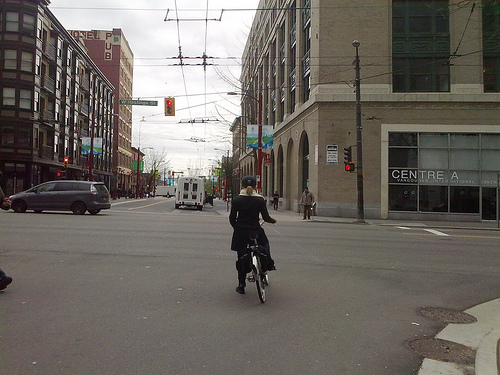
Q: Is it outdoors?
A: Yes, it is outdoors.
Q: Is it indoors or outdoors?
A: It is outdoors.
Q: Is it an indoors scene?
A: No, it is outdoors.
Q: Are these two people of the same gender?
A: No, they are both male and female.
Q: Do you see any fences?
A: No, there are no fences.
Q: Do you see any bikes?
A: Yes, there is a bike.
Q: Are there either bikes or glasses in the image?
A: Yes, there is a bike.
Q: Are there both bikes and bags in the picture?
A: No, there is a bike but no bags.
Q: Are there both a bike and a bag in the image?
A: No, there is a bike but no bags.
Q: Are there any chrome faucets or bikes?
A: Yes, there is a chrome bike.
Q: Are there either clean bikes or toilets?
A: Yes, there is a clean bike.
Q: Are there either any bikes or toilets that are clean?
A: Yes, the bike is clean.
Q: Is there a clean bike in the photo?
A: Yes, there is a clean bike.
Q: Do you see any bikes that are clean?
A: Yes, there is a bike that is clean.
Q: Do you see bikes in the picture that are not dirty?
A: Yes, there is a clean bike.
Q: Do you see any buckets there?
A: No, there are no buckets.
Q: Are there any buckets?
A: No, there are no buckets.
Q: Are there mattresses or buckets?
A: No, there are no buckets or mattresses.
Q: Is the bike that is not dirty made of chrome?
A: Yes, the bike is made of chrome.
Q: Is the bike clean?
A: Yes, the bike is clean.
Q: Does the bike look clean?
A: Yes, the bike is clean.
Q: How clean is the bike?
A: The bike is clean.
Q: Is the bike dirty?
A: No, the bike is clean.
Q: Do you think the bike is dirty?
A: No, the bike is clean.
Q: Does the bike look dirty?
A: No, the bike is clean.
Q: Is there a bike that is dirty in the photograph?
A: No, there is a bike but it is clean.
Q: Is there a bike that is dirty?
A: No, there is a bike but it is clean.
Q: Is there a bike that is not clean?
A: No, there is a bike but it is clean.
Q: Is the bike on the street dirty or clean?
A: The bike is clean.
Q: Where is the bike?
A: The bike is on the street.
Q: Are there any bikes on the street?
A: Yes, there is a bike on the street.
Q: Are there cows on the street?
A: No, there is a bike on the street.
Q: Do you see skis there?
A: No, there are no skis.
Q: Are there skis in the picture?
A: No, there are no skis.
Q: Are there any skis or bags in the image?
A: No, there are no skis or bags.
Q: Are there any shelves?
A: No, there are no shelves.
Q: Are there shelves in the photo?
A: No, there are no shelves.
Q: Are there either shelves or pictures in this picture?
A: No, there are no shelves or pictures.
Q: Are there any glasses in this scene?
A: No, there are no glasses.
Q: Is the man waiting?
A: Yes, the man is waiting.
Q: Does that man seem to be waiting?
A: Yes, the man is waiting.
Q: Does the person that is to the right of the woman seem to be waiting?
A: Yes, the man is waiting.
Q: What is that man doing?
A: The man is waiting.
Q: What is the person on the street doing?
A: The man is waiting.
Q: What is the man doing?
A: The man is waiting.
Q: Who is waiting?
A: The man is waiting.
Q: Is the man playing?
A: No, the man is waiting.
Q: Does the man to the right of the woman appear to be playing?
A: No, the man is waiting.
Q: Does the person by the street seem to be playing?
A: No, the man is waiting.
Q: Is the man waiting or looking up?
A: The man is waiting.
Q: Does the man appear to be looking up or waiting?
A: The man is waiting.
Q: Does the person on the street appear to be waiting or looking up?
A: The man is waiting.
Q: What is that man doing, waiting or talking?
A: The man is waiting.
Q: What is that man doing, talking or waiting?
A: The man is waiting.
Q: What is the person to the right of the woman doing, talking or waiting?
A: The man is waiting.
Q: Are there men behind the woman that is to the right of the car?
A: Yes, there is a man behind the woman.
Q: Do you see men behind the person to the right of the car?
A: Yes, there is a man behind the woman.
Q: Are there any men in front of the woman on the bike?
A: No, the man is behind the woman.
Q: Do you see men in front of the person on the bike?
A: No, the man is behind the woman.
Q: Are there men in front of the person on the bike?
A: No, the man is behind the woman.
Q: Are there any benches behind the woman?
A: No, there is a man behind the woman.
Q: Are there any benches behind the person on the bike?
A: No, there is a man behind the woman.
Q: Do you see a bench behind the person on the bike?
A: No, there is a man behind the woman.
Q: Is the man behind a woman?
A: Yes, the man is behind a woman.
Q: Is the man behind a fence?
A: No, the man is behind a woman.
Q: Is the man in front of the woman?
A: No, the man is behind the woman.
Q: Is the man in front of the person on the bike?
A: No, the man is behind the woman.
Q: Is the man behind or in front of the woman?
A: The man is behind the woman.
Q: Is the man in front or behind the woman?
A: The man is behind the woman.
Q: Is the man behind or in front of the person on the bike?
A: The man is behind the woman.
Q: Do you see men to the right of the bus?
A: Yes, there is a man to the right of the bus.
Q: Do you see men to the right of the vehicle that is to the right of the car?
A: Yes, there is a man to the right of the bus.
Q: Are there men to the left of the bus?
A: No, the man is to the right of the bus.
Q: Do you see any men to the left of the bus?
A: No, the man is to the right of the bus.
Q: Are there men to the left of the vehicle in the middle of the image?
A: No, the man is to the right of the bus.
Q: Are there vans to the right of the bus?
A: No, there is a man to the right of the bus.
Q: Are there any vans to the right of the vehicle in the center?
A: No, there is a man to the right of the bus.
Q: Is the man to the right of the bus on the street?
A: Yes, the man is to the right of the bus.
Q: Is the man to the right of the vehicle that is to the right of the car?
A: Yes, the man is to the right of the bus.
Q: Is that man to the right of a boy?
A: No, the man is to the right of the bus.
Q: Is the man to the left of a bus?
A: No, the man is to the right of a bus.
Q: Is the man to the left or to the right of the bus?
A: The man is to the right of the bus.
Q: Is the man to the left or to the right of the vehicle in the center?
A: The man is to the right of the bus.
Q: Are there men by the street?
A: Yes, there is a man by the street.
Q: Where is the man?
A: The man is on the street.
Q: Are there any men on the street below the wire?
A: Yes, there is a man on the street.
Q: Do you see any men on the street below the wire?
A: Yes, there is a man on the street.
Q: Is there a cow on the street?
A: No, there is a man on the street.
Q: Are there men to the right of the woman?
A: Yes, there is a man to the right of the woman.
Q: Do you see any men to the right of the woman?
A: Yes, there is a man to the right of the woman.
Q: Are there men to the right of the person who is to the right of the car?
A: Yes, there is a man to the right of the woman.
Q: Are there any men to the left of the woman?
A: No, the man is to the right of the woman.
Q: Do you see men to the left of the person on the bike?
A: No, the man is to the right of the woman.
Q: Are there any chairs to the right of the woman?
A: No, there is a man to the right of the woman.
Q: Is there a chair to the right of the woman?
A: No, there is a man to the right of the woman.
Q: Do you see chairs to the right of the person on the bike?
A: No, there is a man to the right of the woman.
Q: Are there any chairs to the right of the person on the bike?
A: No, there is a man to the right of the woman.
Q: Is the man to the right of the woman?
A: Yes, the man is to the right of the woman.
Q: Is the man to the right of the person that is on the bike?
A: Yes, the man is to the right of the woman.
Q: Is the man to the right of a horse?
A: No, the man is to the right of the woman.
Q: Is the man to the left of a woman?
A: No, the man is to the right of a woman.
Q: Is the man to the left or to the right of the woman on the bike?
A: The man is to the right of the woman.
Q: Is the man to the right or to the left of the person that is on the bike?
A: The man is to the right of the woman.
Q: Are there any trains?
A: No, there are no trains.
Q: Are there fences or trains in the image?
A: No, there are no trains or fences.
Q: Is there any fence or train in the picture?
A: No, there are no trains or fences.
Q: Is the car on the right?
A: No, the car is on the left of the image.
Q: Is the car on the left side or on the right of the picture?
A: The car is on the left of the image.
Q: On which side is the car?
A: The car is on the left of the image.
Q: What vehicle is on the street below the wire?
A: The vehicle is a car.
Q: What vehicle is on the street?
A: The vehicle is a car.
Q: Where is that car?
A: The car is on the street.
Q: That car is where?
A: The car is on the street.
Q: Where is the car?
A: The car is on the street.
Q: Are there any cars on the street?
A: Yes, there is a car on the street.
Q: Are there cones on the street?
A: No, there is a car on the street.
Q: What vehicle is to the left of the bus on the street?
A: The vehicle is a car.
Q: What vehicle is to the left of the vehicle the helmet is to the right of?
A: The vehicle is a car.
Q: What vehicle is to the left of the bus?
A: The vehicle is a car.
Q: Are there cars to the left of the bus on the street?
A: Yes, there is a car to the left of the bus.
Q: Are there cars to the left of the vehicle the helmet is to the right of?
A: Yes, there is a car to the left of the bus.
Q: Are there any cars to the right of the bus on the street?
A: No, the car is to the left of the bus.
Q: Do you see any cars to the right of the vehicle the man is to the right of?
A: No, the car is to the left of the bus.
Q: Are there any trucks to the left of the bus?
A: No, there is a car to the left of the bus.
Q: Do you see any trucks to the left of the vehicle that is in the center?
A: No, there is a car to the left of the bus.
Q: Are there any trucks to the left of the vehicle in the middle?
A: No, there is a car to the left of the bus.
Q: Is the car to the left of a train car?
A: No, the car is to the left of a bus.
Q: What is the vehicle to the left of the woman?
A: The vehicle is a car.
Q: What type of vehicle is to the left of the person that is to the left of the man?
A: The vehicle is a car.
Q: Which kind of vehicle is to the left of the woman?
A: The vehicle is a car.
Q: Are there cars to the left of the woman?
A: Yes, there is a car to the left of the woman.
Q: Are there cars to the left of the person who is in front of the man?
A: Yes, there is a car to the left of the woman.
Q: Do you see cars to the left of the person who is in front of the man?
A: Yes, there is a car to the left of the woman.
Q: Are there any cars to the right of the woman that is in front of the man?
A: No, the car is to the left of the woman.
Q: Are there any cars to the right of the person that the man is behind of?
A: No, the car is to the left of the woman.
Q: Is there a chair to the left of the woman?
A: No, there is a car to the left of the woman.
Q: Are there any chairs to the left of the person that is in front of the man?
A: No, there is a car to the left of the woman.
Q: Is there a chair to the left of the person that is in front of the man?
A: No, there is a car to the left of the woman.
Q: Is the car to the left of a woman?
A: Yes, the car is to the left of a woman.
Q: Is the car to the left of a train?
A: No, the car is to the left of a woman.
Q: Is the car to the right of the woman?
A: No, the car is to the left of the woman.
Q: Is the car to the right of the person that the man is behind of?
A: No, the car is to the left of the woman.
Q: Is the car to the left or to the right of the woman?
A: The car is to the left of the woman.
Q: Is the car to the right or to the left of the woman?
A: The car is to the left of the woman.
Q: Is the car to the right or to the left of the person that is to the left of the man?
A: The car is to the left of the woman.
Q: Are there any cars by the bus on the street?
A: Yes, there is a car by the bus.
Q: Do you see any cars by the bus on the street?
A: Yes, there is a car by the bus.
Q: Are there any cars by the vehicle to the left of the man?
A: Yes, there is a car by the bus.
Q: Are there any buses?
A: Yes, there is a bus.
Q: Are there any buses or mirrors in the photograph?
A: Yes, there is a bus.